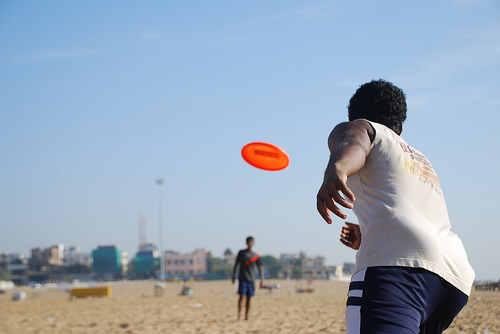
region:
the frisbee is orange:
[238, 125, 295, 184]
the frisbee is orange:
[213, 119, 309, 214]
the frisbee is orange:
[235, 143, 321, 208]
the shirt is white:
[304, 106, 463, 316]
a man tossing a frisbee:
[160, 50, 457, 280]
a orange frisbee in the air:
[235, 102, 325, 252]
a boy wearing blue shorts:
[224, 268, 274, 323]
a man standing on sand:
[200, 185, 342, 327]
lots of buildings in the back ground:
[21, 228, 296, 305]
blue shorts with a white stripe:
[325, 245, 497, 326]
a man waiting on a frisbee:
[225, 130, 339, 298]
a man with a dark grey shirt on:
[216, 200, 319, 322]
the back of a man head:
[329, 57, 447, 142]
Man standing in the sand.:
[231, 230, 264, 317]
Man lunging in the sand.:
[327, 86, 438, 322]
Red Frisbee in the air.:
[241, 131, 296, 175]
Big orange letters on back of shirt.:
[392, 130, 451, 197]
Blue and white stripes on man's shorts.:
[344, 273, 367, 308]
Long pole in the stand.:
[143, 165, 173, 314]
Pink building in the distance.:
[159, 248, 206, 280]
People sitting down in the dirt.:
[279, 276, 316, 298]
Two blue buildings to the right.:
[91, 238, 159, 278]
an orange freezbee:
[241, 122, 291, 181]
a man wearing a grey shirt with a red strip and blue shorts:
[225, 227, 272, 320]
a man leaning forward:
[311, 77, 476, 327]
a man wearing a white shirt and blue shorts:
[308, 75, 480, 330]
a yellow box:
[70, 280, 117, 302]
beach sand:
[72, 297, 232, 332]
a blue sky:
[16, 20, 142, 225]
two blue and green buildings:
[88, 236, 165, 281]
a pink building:
[163, 250, 210, 285]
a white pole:
[146, 168, 178, 285]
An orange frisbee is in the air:
[233, 130, 300, 178]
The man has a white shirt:
[300, 57, 491, 302]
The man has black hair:
[342, 70, 414, 136]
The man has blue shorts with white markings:
[332, 248, 483, 330]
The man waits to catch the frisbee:
[221, 227, 275, 320]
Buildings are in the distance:
[7, 218, 339, 288]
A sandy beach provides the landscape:
[6, 259, 493, 331]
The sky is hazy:
[15, 9, 494, 257]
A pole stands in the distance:
[151, 168, 174, 285]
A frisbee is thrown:
[222, 56, 487, 321]